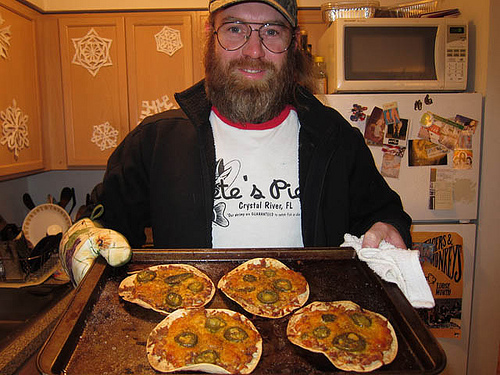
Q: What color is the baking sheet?
A: Brown.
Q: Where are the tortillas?
A: On the baking sheet.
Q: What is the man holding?
A: The baking sheet.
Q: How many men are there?
A: One.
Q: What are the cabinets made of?
A: Wood.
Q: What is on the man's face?
A: Glasses.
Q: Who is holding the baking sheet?
A: The man.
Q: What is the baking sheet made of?
A: Metal.